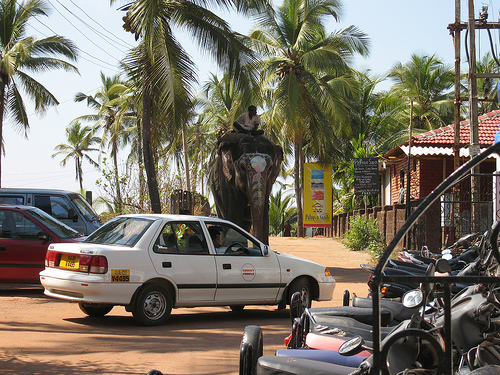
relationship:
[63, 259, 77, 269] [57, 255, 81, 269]
text on license plate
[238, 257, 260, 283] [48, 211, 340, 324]
symbol on car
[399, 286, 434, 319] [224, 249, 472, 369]
mirror on motorcycle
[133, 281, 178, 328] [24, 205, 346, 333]
tire on car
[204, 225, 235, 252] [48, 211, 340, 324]
driver on car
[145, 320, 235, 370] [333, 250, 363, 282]
shadow on tree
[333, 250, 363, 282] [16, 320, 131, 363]
tree on ground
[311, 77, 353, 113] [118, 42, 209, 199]
leaves on tree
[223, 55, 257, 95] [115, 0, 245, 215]
leaves on palm trees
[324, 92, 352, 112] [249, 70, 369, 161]
leaves on tree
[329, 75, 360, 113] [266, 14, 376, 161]
leaves on tree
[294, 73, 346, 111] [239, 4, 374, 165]
leaves on tree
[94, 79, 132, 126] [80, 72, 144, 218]
leaves on palm tree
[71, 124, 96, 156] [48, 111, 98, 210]
leaves on palm tree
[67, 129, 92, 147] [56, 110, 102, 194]
leaves on palm tree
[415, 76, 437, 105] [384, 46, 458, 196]
leaves on palm tree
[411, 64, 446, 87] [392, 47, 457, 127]
leaves on palm tree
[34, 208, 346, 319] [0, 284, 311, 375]
car on ground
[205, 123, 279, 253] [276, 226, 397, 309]
elephant on road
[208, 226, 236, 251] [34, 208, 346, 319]
person in car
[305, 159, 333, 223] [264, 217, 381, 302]
sign on road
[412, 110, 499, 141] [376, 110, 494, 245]
tile roof on building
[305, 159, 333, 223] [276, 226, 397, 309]
sign on road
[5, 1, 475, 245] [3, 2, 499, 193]
palm trees under sky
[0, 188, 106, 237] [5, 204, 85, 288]
car parked next to car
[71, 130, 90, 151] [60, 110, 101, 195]
leaves of palm tree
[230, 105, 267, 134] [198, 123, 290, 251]
man seated on elephant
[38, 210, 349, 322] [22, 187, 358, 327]
side of car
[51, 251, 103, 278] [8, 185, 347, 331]
license plate on car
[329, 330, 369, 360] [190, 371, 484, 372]
mirror of bike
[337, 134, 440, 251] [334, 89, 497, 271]
wall in front of building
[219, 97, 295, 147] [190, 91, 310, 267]
man on top of an elephant